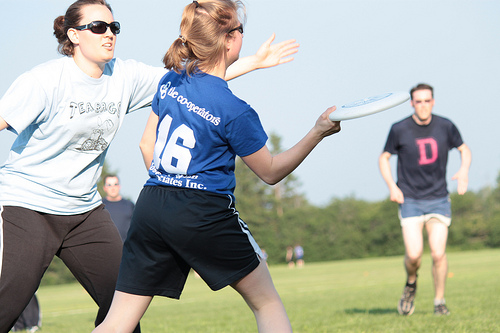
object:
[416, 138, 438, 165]
letter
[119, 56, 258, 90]
arm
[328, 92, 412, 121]
frisbee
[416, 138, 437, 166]
d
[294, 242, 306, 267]
people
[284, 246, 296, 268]
people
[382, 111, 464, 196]
shirt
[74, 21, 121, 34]
sunglasses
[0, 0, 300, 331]
people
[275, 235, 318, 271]
two people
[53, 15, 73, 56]
ponytail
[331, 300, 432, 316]
shadow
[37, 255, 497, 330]
grass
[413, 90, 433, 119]
face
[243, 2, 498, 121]
sky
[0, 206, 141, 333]
pant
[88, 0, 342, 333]
girl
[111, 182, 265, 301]
shorts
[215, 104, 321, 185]
arm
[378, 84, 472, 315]
man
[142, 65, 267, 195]
shirt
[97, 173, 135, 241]
man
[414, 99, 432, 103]
sunglasses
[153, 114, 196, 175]
number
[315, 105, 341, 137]
hand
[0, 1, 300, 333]
female defender